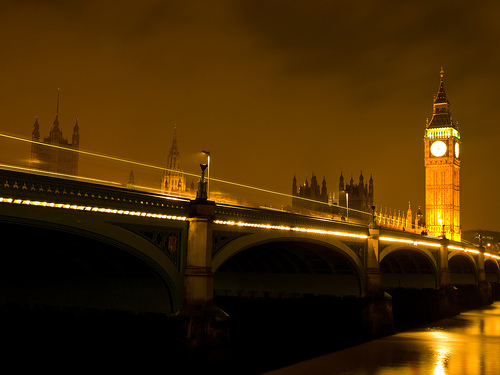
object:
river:
[268, 304, 499, 375]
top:
[424, 66, 458, 128]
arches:
[26, 218, 184, 285]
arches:
[379, 243, 441, 290]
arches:
[448, 251, 479, 285]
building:
[291, 171, 372, 222]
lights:
[294, 227, 367, 239]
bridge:
[0, 167, 500, 302]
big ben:
[423, 67, 460, 243]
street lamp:
[197, 151, 211, 199]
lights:
[77, 205, 85, 211]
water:
[337, 350, 437, 373]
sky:
[1, 1, 500, 228]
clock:
[430, 140, 447, 156]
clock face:
[430, 141, 446, 157]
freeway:
[0, 164, 499, 253]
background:
[0, 0, 493, 242]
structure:
[161, 124, 185, 194]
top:
[169, 123, 180, 156]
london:
[1, 2, 497, 372]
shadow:
[0, 272, 498, 371]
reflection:
[392, 314, 499, 375]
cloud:
[0, 0, 499, 231]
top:
[339, 170, 374, 196]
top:
[292, 172, 328, 200]